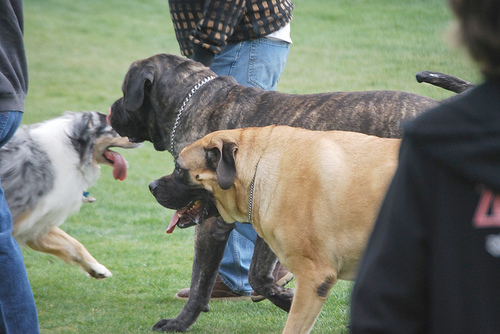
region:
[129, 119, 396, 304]
the dog is golden brown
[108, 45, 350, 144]
the dog is brown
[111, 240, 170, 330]
the grass is green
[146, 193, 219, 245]
the tongue is pink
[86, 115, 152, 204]
the tongue is sticking out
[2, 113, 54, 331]
the jeans are blue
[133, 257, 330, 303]
the shoes are brown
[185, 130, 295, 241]
the dog is wearing a chain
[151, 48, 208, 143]
the chain is silver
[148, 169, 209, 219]
the nose is brown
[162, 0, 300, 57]
Black sweater with gold squares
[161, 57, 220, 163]
Silver chain on dark large dog neck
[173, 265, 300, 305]
Two brown shoes on man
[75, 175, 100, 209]
Blue dog tag on white collie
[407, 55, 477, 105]
Tail of dark dog over man's shoulder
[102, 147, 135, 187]
Large pink tongue on white collie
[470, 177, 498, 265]
Red and white letters on black hoodie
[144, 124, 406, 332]
Large beige dog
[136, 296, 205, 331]
Paw of large dark dog on grass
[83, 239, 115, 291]
Paw of white collie not touching grass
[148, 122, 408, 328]
a brown and black dog at the park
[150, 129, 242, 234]
the snout and ears are black on the dog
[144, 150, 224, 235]
the dog's pink tongue is hanging out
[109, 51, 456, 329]
a brindled mastiff has a silver chain collar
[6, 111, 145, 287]
the collie's tongue is hanging out the side of his mouth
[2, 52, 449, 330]
three dogs are playing in the park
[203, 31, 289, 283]
the man behind the dogs has blue jeans on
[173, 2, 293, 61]
the man is wearing a checkered sweater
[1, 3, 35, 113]
this person is wearing a gray sweater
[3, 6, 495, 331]
green grass is in the park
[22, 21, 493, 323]
three dogs with their tongue out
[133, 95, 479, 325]
a tan colored dog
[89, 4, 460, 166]
a chocolate color dog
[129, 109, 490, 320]
a dog with his toung out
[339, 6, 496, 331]
a women wearing a black jacket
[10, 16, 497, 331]
three dogs on grass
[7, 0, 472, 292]
three dogs walking on grass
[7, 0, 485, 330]
dogs and people standing on grass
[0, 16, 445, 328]
three dogs and three people standing on grass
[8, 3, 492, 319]
people and dogs walking on grass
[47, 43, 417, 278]
three dogs with three people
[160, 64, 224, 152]
silver chain around dogs neck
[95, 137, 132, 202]
dog with tongue hanging out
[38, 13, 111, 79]
well manicured green grass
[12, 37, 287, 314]
two people wearing blue jeans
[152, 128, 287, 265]
brown dog with black nose and ears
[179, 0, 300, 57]
person with a checkered sweat shirt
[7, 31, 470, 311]
three people letting their dogs play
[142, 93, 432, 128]
dark brown dog with light brown patches of fur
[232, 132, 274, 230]
silver chain around tan dogs neck